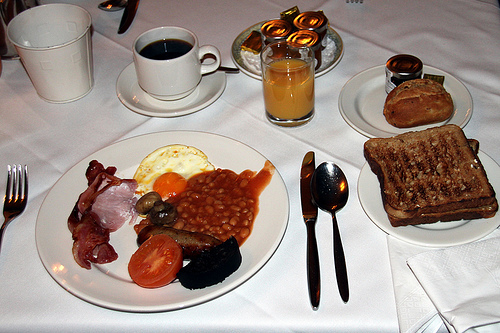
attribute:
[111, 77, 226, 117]
saucer — round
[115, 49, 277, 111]
saucer — round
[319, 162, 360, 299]
spoon — stainless, steel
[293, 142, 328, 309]
knife — stainless, steel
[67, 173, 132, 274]
bacon — fried 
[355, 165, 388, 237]
saucer — white 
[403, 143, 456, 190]
bread — sliced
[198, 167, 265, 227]
beans — baked 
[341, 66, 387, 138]
saucer — white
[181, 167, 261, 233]
beans — saucy , baked 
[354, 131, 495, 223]
toast — grilled 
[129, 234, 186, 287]
tomato slice — sliced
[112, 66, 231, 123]
saucer — white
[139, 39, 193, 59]
coffee — black 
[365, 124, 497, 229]
bread — toasted 